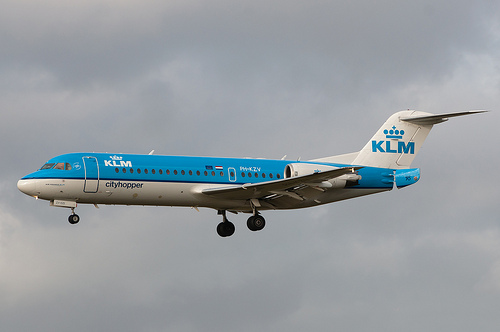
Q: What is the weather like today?
A: It is cloudy.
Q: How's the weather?
A: It is cloudy.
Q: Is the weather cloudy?
A: Yes, it is cloudy.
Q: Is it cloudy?
A: Yes, it is cloudy.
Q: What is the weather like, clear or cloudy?
A: It is cloudy.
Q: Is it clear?
A: No, it is cloudy.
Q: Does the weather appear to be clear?
A: No, it is cloudy.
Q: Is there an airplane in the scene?
A: Yes, there is an airplane.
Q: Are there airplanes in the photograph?
A: Yes, there is an airplane.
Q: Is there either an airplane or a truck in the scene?
A: Yes, there is an airplane.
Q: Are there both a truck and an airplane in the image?
A: No, there is an airplane but no trucks.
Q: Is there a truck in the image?
A: No, there are no trucks.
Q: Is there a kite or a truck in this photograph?
A: No, there are no trucks or kites.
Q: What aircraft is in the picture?
A: The aircraft is an airplane.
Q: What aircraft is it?
A: The aircraft is an airplane.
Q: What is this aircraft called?
A: This is an airplane.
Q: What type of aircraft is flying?
A: The aircraft is an airplane.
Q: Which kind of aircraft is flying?
A: The aircraft is an airplane.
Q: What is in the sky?
A: The plane is in the sky.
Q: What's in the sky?
A: The plane is in the sky.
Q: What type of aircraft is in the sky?
A: The aircraft is an airplane.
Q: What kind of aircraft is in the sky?
A: The aircraft is an airplane.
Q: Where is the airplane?
A: The airplane is in the sky.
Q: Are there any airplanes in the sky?
A: Yes, there is an airplane in the sky.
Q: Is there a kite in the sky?
A: No, there is an airplane in the sky.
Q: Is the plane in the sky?
A: Yes, the plane is in the sky.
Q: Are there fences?
A: No, there are no fences.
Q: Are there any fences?
A: No, there are no fences.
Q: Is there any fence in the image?
A: No, there are no fences.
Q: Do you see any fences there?
A: No, there are no fences.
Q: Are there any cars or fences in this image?
A: No, there are no fences or cars.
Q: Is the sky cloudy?
A: Yes, the sky is cloudy.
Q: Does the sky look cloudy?
A: Yes, the sky is cloudy.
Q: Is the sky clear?
A: No, the sky is cloudy.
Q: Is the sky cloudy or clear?
A: The sky is cloudy.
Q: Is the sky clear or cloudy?
A: The sky is cloudy.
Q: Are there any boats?
A: No, there are no boats.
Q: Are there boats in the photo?
A: No, there are no boats.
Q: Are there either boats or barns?
A: No, there are no boats or barns.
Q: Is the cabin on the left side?
A: Yes, the cabin is on the left of the image.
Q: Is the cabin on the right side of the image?
A: No, the cabin is on the left of the image.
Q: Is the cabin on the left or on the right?
A: The cabin is on the left of the image.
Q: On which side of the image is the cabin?
A: The cabin is on the left of the image.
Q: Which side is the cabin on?
A: The cabin is on the left of the image.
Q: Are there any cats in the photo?
A: No, there are no cats.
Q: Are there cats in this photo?
A: No, there are no cats.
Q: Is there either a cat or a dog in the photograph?
A: No, there are no cats or dogs.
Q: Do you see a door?
A: Yes, there is a door.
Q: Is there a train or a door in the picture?
A: Yes, there is a door.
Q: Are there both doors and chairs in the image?
A: No, there is a door but no chairs.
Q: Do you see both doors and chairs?
A: No, there is a door but no chairs.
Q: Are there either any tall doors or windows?
A: Yes, there is a tall door.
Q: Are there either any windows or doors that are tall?
A: Yes, the door is tall.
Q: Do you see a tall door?
A: Yes, there is a tall door.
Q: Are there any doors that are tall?
A: Yes, there is a door that is tall.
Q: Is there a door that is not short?
A: Yes, there is a tall door.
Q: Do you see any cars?
A: No, there are no cars.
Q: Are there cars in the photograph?
A: No, there are no cars.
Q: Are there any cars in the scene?
A: No, there are no cars.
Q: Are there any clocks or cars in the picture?
A: No, there are no cars or clocks.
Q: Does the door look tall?
A: Yes, the door is tall.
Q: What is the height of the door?
A: The door is tall.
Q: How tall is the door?
A: The door is tall.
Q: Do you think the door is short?
A: No, the door is tall.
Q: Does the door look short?
A: No, the door is tall.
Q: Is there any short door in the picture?
A: No, there is a door but it is tall.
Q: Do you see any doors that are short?
A: No, there is a door but it is tall.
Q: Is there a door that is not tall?
A: No, there is a door but it is tall.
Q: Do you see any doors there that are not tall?
A: No, there is a door but it is tall.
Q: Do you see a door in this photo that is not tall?
A: No, there is a door but it is tall.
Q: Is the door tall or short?
A: The door is tall.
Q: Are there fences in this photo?
A: No, there are no fences.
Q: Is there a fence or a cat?
A: No, there are no fences or cats.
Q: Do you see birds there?
A: No, there are no birds.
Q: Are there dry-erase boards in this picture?
A: No, there are no dry-erase boards.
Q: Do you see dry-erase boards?
A: No, there are no dry-erase boards.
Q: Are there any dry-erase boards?
A: No, there are no dry-erase boards.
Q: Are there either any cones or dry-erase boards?
A: No, there are no dry-erase boards or cones.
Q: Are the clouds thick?
A: Yes, the clouds are thick.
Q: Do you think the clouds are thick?
A: Yes, the clouds are thick.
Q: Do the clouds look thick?
A: Yes, the clouds are thick.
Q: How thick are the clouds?
A: The clouds are thick.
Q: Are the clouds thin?
A: No, the clouds are thick.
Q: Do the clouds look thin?
A: No, the clouds are thick.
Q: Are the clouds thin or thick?
A: The clouds are thick.